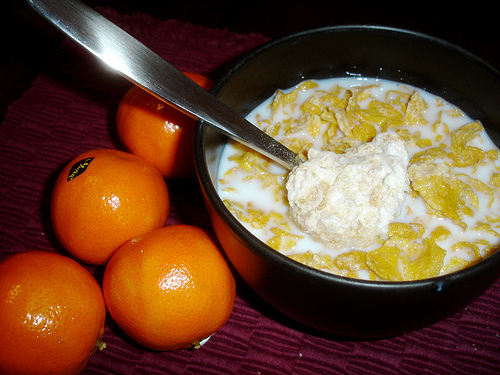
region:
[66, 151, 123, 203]
Sunkist sticker on citrus fruit.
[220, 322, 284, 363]
Purple embroidered plate mat.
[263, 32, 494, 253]
Clump of sugar in bowl.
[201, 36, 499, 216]
Silver eating tool in cereal bowl.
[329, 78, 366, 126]
Corn flakes in bowl.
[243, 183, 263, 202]
White milk in bowl.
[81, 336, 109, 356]
Stem on citrus fruit.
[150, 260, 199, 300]
Reflection of light on orange.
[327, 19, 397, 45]
Reflection of light on bowl.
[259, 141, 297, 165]
Powder substance on silver spoon.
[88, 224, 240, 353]
this is a orange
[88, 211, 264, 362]
the orange is orange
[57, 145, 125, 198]
a sticker on the orange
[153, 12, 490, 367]
this is a bowl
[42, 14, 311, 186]
this is a piece of silverware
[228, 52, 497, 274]
milk is in the bowl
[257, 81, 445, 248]
cereal in the bowkl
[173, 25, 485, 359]
the bowl is black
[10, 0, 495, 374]
group of oranges next to a bowl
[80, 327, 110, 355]
green stem on orange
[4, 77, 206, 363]
oranges on a table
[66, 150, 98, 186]
a black label on a orange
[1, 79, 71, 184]
ared matt on a table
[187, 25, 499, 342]
a black bowl on a table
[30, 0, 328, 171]
a silver spoon in a bowl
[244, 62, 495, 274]
milk in a bowl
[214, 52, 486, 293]
corn flakes in a bowl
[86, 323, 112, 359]
a stem on a orange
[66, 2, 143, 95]
a reflection on a spoon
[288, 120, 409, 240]
whip cream in a bowl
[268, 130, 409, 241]
Ice cream in a pan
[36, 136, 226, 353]
Oranges on a table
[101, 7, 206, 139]
Handle of a large spoon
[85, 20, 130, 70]
Reflection off of a spoon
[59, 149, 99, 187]
Label sticker on an orange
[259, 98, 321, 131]
Milk in a sauce pan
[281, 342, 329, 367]
Red cover on a table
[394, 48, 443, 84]
Inside of a sauce pan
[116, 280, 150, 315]
Outside peel of an orange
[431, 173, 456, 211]
Pieces of orange in a pan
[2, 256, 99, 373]
the bright orange unpeeled orange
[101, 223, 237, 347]
the bright orange unpeeled orange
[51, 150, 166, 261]
the bright orange unpeeled orange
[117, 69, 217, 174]
the bright orange unpeeled orange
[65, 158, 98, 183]
the black sticker on the orange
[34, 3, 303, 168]
the silver handle in the bowl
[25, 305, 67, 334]
the light reflective spot on the orange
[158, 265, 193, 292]
the light reflective spot on the orange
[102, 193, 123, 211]
the light reflective spot on the orange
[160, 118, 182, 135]
the light reflective spot on the orange